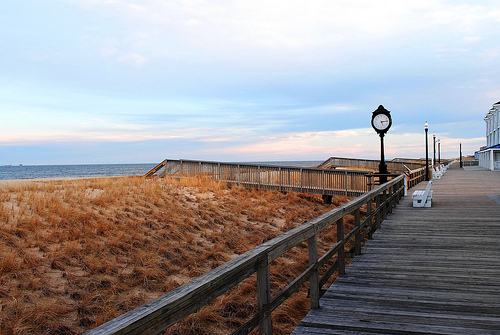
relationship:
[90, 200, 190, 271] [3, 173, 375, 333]
dried grass on sand dune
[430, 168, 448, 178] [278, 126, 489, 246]
bench on pier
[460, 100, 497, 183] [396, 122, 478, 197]
building on pier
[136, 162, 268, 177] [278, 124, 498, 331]
stairway on pier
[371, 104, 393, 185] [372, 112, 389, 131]
clock tower surrounding clock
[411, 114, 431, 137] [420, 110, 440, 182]
street light on post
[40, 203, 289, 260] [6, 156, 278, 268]
brush on a beach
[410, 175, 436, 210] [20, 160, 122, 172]
bench facing ocean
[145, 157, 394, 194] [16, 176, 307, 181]
boardwalk to beach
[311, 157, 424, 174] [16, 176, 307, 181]
boardwalk to beach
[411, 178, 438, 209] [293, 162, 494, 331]
bench on boardwalk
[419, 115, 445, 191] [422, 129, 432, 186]
lights on pole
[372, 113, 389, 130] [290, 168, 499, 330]
clock on corner sidewalk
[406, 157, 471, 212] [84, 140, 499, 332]
benches on sidewalk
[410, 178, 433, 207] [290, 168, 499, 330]
bench on sidewalk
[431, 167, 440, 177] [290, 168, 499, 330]
bench on sidewalk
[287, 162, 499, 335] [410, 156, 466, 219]
boardwalk with benches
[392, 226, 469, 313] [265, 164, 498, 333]
slats of boardwalk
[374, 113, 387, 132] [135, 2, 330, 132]
clock on clock tower